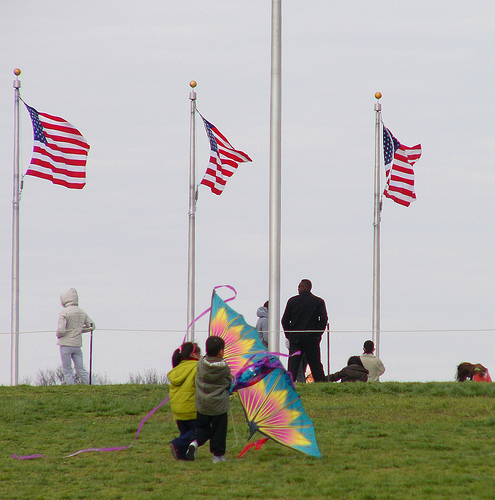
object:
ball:
[13, 67, 22, 76]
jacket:
[324, 363, 368, 385]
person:
[55, 287, 95, 384]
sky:
[0, 1, 495, 386]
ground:
[338, 172, 393, 241]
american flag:
[379, 118, 423, 214]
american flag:
[195, 109, 252, 208]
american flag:
[16, 93, 91, 200]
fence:
[88, 322, 495, 386]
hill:
[0, 379, 495, 500]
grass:
[0, 370, 495, 500]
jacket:
[55, 288, 96, 348]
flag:
[380, 119, 422, 208]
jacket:
[166, 360, 199, 421]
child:
[166, 342, 202, 460]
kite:
[10, 283, 322, 463]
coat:
[56, 287, 96, 347]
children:
[166, 335, 233, 465]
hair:
[205, 335, 225, 357]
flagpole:
[267, 0, 282, 360]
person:
[281, 278, 329, 382]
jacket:
[281, 292, 328, 341]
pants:
[287, 338, 327, 383]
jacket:
[193, 355, 233, 416]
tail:
[9, 284, 238, 459]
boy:
[186, 335, 232, 463]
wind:
[7, 59, 473, 251]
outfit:
[56, 287, 96, 385]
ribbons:
[228, 349, 301, 395]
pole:
[12, 68, 20, 388]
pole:
[188, 79, 198, 344]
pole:
[372, 90, 382, 359]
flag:
[23, 104, 90, 189]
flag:
[194, 108, 255, 196]